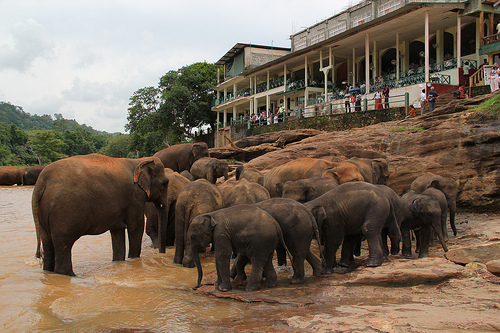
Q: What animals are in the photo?
A: Elephants.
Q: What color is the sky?
A: Grey.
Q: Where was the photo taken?
A: Zoo.